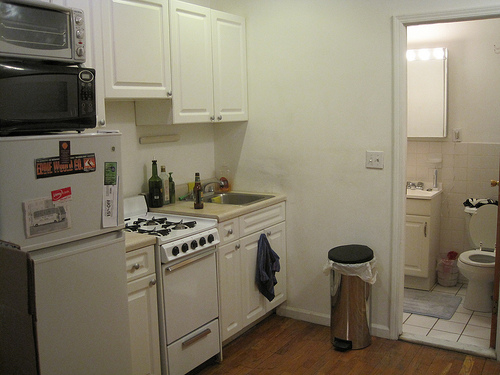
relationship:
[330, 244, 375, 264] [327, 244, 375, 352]
lid of trashcan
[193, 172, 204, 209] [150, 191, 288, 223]
bottle on counter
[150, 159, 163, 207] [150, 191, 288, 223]
bottle on counter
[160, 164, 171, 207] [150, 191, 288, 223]
bottle on counter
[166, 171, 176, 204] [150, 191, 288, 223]
bottle on counter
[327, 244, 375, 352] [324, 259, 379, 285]
trashcan has a bag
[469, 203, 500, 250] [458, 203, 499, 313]
lid of toilet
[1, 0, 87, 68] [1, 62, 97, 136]
microwave on microwave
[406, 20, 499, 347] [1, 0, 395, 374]
bathroom beside kitchen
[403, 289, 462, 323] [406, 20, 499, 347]
mat in bathroom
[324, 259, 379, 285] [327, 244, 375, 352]
bag covered by trashcan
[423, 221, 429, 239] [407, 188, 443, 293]
handle on cabinet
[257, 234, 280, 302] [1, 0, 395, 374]
towel for kitchen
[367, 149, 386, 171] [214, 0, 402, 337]
lightswitch on wall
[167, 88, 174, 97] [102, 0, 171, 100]
handle on cupboards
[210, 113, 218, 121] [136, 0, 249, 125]
handle on cupboards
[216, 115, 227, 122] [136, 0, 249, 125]
handle on cupboards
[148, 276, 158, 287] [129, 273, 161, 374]
handle on cupboards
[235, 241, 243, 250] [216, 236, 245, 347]
handle on cupboards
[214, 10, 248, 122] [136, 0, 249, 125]
door of cupboards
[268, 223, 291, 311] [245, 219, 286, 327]
door of cupboard